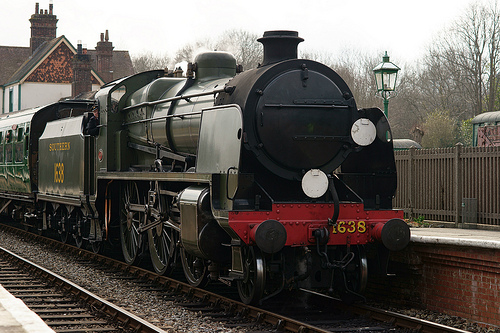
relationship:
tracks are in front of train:
[1, 209, 478, 332] [2, 31, 414, 303]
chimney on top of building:
[95, 28, 118, 82] [1, 3, 140, 130]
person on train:
[84, 105, 103, 135] [2, 31, 414, 303]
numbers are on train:
[52, 161, 67, 184] [2, 31, 414, 303]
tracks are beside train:
[1, 209, 478, 332] [2, 31, 414, 303]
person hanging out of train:
[84, 105, 103, 135] [2, 31, 414, 303]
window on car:
[16, 125, 25, 142] [1, 105, 44, 234]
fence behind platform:
[384, 142, 500, 229] [390, 214, 500, 326]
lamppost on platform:
[375, 52, 399, 123] [390, 214, 500, 326]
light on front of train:
[302, 167, 329, 199] [2, 31, 414, 303]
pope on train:
[118, 87, 233, 113] [2, 31, 414, 303]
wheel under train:
[117, 182, 144, 265] [2, 31, 414, 303]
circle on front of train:
[350, 117, 377, 146] [2, 31, 414, 303]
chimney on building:
[95, 28, 118, 82] [1, 3, 140, 130]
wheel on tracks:
[117, 182, 144, 265] [1, 209, 478, 332]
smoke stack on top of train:
[258, 31, 305, 65] [2, 31, 414, 303]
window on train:
[16, 125, 25, 142] [2, 31, 414, 303]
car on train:
[1, 105, 44, 234] [2, 31, 414, 303]